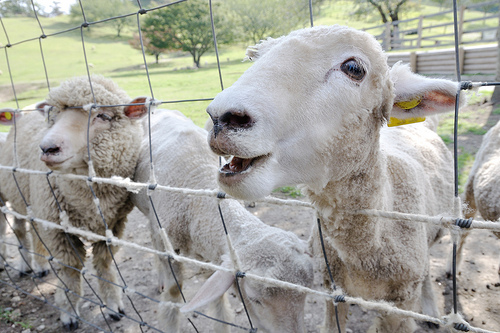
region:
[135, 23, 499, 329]
The sheep that have already been shaved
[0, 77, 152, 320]
The unshaved sheep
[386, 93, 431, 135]
The tag in the shaved sheep's ear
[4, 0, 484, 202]
The grass field in the background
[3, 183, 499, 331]
The dirt patch the sheep are standing on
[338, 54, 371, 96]
The eye nearest the the camera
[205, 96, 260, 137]
The nose of the sheep nearest the camera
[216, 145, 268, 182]
The mouth of the nearest sheep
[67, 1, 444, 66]
The trees in the background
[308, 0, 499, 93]
The fence behind the sheep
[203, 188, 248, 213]
black line on wire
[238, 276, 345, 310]
white covering on the wire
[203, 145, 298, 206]
open mouth of sheep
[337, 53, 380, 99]
large black shiny eyes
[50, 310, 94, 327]
black bottom of feet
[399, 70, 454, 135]
pink inside of ears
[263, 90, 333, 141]
white wool on sheep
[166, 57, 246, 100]
shadow cast on ground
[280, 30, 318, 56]
bump on front of sheep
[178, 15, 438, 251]
large white sheep in pen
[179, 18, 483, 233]
the face of a sheep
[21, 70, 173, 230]
the sheep is white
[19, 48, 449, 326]
there are three sheep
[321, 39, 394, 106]
the sheep's eye is black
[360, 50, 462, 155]
the sheep has a yellow ear tag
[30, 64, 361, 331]
the sheep are white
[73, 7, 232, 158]
trees in the background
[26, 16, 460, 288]
the sheep are behind a fence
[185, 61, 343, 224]
the sheep's mouth is open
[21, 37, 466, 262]
two sheep looking at camera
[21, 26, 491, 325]
sheep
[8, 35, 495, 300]
sheep behind a fence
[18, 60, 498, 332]
a group of sheep up against a fence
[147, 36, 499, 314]
the sheep are recently sheared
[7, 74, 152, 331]
the left most sheep is the only one not recently sheared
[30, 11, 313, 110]
a field is behind the animals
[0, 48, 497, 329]
animals in a pen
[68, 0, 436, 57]
trees are in the background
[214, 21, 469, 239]
a sheep sticks it's head through the fence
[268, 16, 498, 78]
a fence is behind the animals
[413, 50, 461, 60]
a wooden timber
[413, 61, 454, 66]
a wooden timber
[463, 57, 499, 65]
a wooden timber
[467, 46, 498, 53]
a wooden timber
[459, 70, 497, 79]
a wooden timber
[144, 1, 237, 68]
a tree in a distance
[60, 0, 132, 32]
a tree in a distance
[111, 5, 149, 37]
a tree in a distance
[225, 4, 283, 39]
a tree in a distance